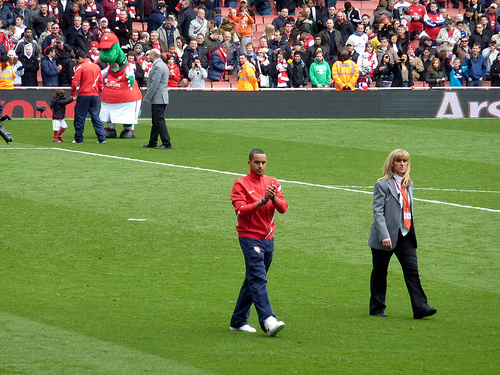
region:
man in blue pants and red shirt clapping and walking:
[226, 145, 289, 336]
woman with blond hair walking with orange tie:
[363, 149, 438, 324]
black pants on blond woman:
[368, 225, 433, 315]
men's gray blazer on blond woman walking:
[371, 170, 416, 253]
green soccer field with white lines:
[7, 118, 499, 365]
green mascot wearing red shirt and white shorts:
[91, 33, 139, 135]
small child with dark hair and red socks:
[48, 88, 83, 146]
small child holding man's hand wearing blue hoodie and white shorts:
[47, 86, 78, 145]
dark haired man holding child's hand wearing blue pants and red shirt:
[66, 48, 108, 148]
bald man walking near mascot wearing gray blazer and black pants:
[139, 45, 179, 146]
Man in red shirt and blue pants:
[229, 148, 289, 338]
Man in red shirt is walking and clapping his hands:
[227, 147, 287, 337]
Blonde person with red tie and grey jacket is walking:
[366, 148, 440, 321]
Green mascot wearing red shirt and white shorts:
[94, 38, 142, 136]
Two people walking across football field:
[5, 144, 477, 373]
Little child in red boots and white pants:
[48, 36, 173, 150]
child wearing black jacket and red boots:
[49, 88, 80, 144]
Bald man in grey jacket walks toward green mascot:
[95, 35, 171, 150]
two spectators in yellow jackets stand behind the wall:
[230, 43, 382, 89]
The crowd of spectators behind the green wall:
[0, 37, 498, 92]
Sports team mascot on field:
[90, 28, 140, 142]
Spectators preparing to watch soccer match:
[5, 5, 492, 102]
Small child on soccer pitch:
[47, 85, 77, 143]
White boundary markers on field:
[50, 143, 497, 228]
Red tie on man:
[397, 180, 416, 234]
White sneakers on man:
[215, 317, 299, 335]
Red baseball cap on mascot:
[95, 28, 120, 51]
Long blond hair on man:
[377, 148, 413, 189]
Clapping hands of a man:
[250, 183, 288, 212]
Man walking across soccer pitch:
[225, 148, 297, 345]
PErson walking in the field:
[205, 129, 317, 351]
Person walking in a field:
[335, 124, 480, 348]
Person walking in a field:
[138, 41, 180, 142]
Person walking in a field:
[65, 54, 99, 138]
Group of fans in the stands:
[421, 2, 498, 97]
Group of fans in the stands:
[340, 4, 425, 96]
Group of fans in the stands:
[275, 0, 360, 94]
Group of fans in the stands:
[200, 1, 281, 98]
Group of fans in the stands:
[127, 1, 206, 96]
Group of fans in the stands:
[10, 4, 211, 94]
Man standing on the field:
[222, 138, 279, 374]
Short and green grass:
[101, 217, 166, 282]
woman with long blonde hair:
[379, 136, 430, 212]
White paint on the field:
[110, 148, 191, 177]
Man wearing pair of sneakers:
[253, 310, 323, 350]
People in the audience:
[230, 10, 457, 105]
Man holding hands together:
[252, 175, 297, 217]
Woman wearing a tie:
[394, 190, 423, 245]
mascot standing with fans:
[92, 20, 146, 161]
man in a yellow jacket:
[331, 45, 366, 90]